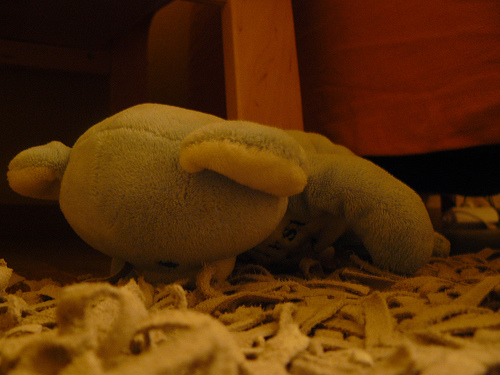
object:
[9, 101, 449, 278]
bear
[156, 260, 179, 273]
eye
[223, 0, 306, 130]
chair leg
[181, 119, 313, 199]
ear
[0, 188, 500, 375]
floor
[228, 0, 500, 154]
chair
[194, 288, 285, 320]
flooring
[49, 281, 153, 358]
threads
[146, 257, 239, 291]
nose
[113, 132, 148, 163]
fur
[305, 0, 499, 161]
fabric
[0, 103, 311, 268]
head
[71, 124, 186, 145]
seam